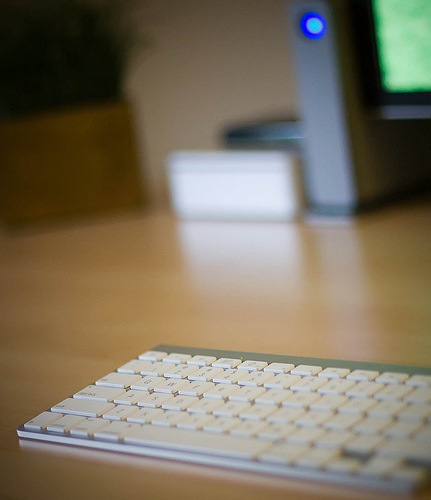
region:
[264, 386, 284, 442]
There are bright white keys on the keyboard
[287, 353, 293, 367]
There is silver that is on this keyboard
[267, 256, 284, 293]
There is a light brown desk in the photo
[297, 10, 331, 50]
There is a blue light in the distance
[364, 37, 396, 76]
There is a monitor of the computer here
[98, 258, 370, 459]
This photo was taken in Dayton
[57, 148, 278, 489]
This photo has a lot of detail to it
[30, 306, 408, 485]
silver and white keyboard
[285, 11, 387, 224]
blurry computer tower with blue light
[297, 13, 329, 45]
blue light on computer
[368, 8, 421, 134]
corner of monitor with green screen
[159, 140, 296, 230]
white square that is blurry in background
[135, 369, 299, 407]
qwerty keys on keyboard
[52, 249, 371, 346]
light brown wooden table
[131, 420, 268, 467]
white spacebar on keyboard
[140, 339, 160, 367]
escape key on keyboard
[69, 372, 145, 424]
caps lock key on keyboard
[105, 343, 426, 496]
small keyboard on table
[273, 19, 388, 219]
grey box on table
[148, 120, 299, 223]
white Mac on table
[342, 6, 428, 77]
monitor next to computer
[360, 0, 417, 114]
monitor has black frame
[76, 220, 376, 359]
wooden table with computer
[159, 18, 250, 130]
brown wall behind computer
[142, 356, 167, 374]
white button on keyboard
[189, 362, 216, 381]
white button on keyboard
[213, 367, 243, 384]
white button on keyboard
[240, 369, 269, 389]
white button on keyboard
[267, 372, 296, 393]
white button on keyboard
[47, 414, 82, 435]
white button on keyboard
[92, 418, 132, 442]
white button on keyboard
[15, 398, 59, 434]
white button on keyboard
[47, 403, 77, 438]
white button on keyboard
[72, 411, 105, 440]
white button on keyboard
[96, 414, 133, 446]
white button on keyboard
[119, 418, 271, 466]
white button on keyboard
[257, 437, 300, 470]
white button on keyboard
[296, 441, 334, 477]
white button on keyboard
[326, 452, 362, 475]
white button on keyboard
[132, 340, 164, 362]
white button on keyboard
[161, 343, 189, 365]
white button on keyboard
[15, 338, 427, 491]
an Apple Magic keyboard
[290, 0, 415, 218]
an external hard drive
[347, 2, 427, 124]
a dekstop computer monitor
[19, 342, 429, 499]
a bluetooth computer keyboard